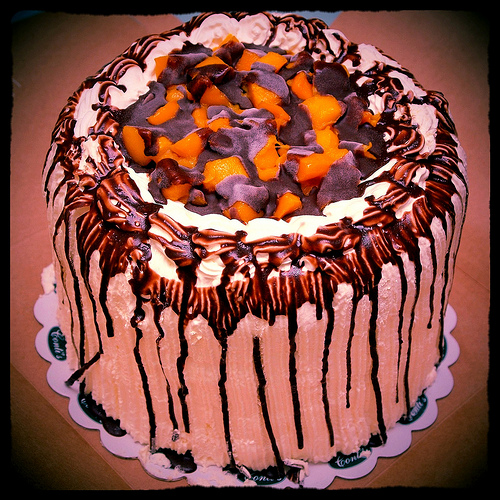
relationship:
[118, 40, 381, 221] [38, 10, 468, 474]
icing on cake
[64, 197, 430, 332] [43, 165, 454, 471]
sauce on side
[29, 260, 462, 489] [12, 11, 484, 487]
base on table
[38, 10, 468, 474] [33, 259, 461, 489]
cake sitting on paper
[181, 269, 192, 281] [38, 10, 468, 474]
sauce on cake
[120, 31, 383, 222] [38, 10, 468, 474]
fruit on top of cake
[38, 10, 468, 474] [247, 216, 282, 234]
cake covered in icing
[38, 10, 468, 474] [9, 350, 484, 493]
cake near countertop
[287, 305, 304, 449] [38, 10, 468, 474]
drizzle adorning cake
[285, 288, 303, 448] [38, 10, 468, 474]
drizzle adorning cake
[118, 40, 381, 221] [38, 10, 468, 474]
icing topping cake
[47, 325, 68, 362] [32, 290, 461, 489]
circle printed on cardboard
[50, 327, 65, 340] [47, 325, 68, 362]
letter printed on circle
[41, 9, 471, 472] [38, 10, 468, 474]
syrup topping cake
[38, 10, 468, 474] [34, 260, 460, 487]
cake sitting on top of paper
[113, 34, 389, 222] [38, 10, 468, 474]
top adorning cake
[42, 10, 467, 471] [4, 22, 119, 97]
cake on table